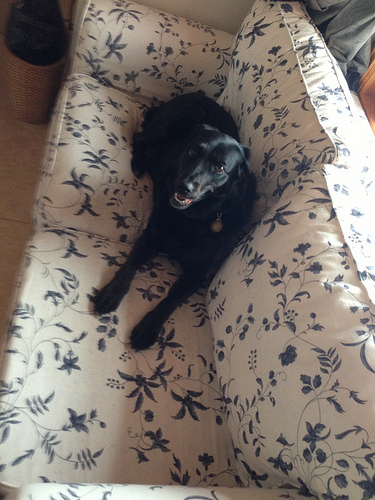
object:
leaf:
[312, 373, 322, 388]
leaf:
[297, 373, 312, 385]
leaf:
[300, 385, 313, 394]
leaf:
[325, 394, 345, 412]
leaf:
[346, 387, 367, 405]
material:
[202, 162, 373, 498]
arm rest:
[73, 0, 243, 108]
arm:
[112, 228, 155, 295]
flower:
[170, 388, 209, 420]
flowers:
[278, 343, 296, 369]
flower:
[58, 354, 81, 374]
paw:
[90, 288, 121, 314]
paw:
[130, 155, 147, 177]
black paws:
[128, 308, 168, 347]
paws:
[130, 310, 165, 348]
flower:
[143, 40, 155, 58]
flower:
[245, 15, 276, 48]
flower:
[262, 200, 300, 235]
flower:
[61, 167, 93, 192]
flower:
[288, 238, 310, 256]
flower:
[137, 425, 169, 454]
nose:
[178, 181, 195, 193]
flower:
[313, 88, 331, 106]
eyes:
[189, 141, 206, 161]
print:
[241, 61, 287, 130]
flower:
[99, 27, 133, 70]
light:
[342, 99, 371, 189]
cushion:
[231, 6, 364, 174]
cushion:
[236, 184, 368, 492]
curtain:
[307, 2, 374, 79]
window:
[356, 78, 374, 119]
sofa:
[0, 0, 374, 498]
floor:
[1, 105, 49, 348]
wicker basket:
[5, 38, 67, 124]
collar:
[208, 207, 222, 233]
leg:
[89, 233, 165, 320]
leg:
[125, 273, 206, 351]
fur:
[156, 122, 181, 144]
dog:
[84, 85, 255, 354]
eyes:
[210, 160, 225, 176]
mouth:
[170, 184, 200, 205]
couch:
[3, 2, 372, 498]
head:
[167, 124, 244, 214]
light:
[180, 131, 248, 200]